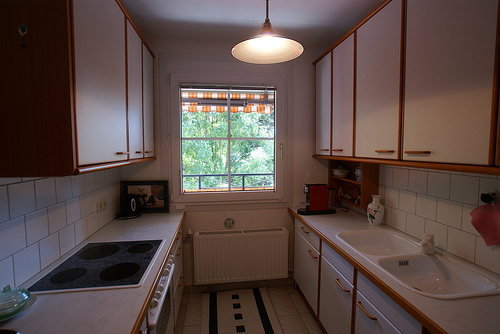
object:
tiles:
[267, 294, 302, 318]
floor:
[174, 273, 325, 333]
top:
[25, 230, 168, 293]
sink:
[378, 253, 500, 301]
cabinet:
[399, 2, 497, 167]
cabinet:
[349, 3, 401, 161]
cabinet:
[330, 32, 354, 156]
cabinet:
[312, 50, 333, 157]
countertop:
[287, 204, 498, 333]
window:
[180, 88, 279, 191]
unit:
[192, 225, 289, 286]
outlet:
[96, 196, 110, 212]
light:
[227, 0, 313, 71]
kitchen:
[0, 4, 497, 333]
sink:
[382, 246, 496, 296]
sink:
[334, 223, 424, 255]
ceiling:
[111, 0, 386, 68]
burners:
[21, 237, 168, 296]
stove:
[147, 257, 182, 334]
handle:
[149, 259, 180, 328]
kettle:
[117, 189, 150, 220]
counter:
[1, 209, 185, 329]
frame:
[396, 4, 499, 175]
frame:
[353, 0, 407, 163]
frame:
[328, 32, 356, 161]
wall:
[0, 165, 125, 290]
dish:
[0, 284, 30, 312]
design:
[366, 205, 379, 224]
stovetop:
[18, 229, 160, 294]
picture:
[14, 22, 30, 56]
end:
[4, 4, 78, 177]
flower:
[364, 204, 379, 214]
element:
[99, 259, 140, 282]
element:
[128, 236, 153, 256]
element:
[46, 261, 91, 285]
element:
[78, 240, 122, 259]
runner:
[201, 284, 287, 333]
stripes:
[198, 284, 277, 333]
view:
[178, 85, 273, 190]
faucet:
[417, 234, 436, 256]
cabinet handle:
[401, 150, 433, 156]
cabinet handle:
[372, 148, 394, 154]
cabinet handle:
[330, 148, 345, 153]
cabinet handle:
[317, 147, 329, 152]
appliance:
[295, 180, 334, 216]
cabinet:
[294, 221, 319, 313]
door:
[398, 2, 496, 166]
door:
[353, 4, 398, 161]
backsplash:
[5, 172, 184, 333]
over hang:
[178, 88, 273, 114]